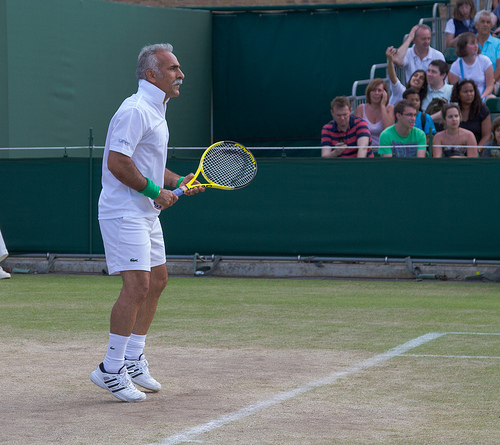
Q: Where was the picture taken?
A: A tennis court.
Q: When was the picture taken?
A: Daytime.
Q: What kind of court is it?
A: Turf.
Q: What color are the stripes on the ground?
A: White.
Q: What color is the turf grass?
A: Green.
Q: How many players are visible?
A: One.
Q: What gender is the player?
A: Male.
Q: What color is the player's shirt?
A: White.